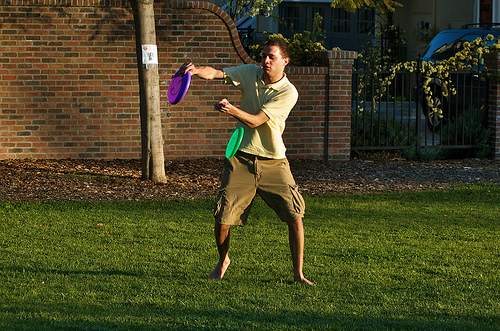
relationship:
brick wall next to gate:
[0, 0, 359, 160] [349, 52, 488, 155]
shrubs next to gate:
[349, 102, 491, 157] [349, 52, 488, 155]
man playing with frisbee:
[181, 37, 316, 287] [222, 127, 245, 159]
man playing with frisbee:
[181, 37, 316, 287] [165, 60, 192, 104]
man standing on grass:
[181, 37, 316, 287] [1, 181, 498, 329]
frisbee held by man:
[165, 60, 192, 104] [181, 37, 316, 287]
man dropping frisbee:
[181, 37, 316, 287] [222, 127, 245, 159]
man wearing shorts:
[181, 37, 316, 287] [213, 150, 305, 225]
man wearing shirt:
[181, 37, 316, 287] [219, 63, 300, 160]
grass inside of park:
[1, 181, 498, 329] [1, 1, 499, 331]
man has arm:
[181, 37, 316, 287] [227, 87, 298, 128]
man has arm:
[181, 37, 316, 287] [194, 63, 254, 82]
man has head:
[181, 37, 316, 287] [259, 37, 291, 76]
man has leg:
[181, 37, 316, 287] [286, 213, 306, 275]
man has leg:
[181, 37, 316, 287] [213, 220, 232, 256]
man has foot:
[181, 37, 316, 287] [294, 272, 317, 288]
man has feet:
[181, 37, 316, 287] [210, 253, 233, 278]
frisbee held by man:
[222, 127, 245, 159] [181, 37, 316, 287]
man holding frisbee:
[181, 37, 316, 287] [222, 127, 245, 159]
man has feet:
[181, 37, 316, 287] [210, 253, 317, 288]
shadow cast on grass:
[2, 296, 498, 331] [1, 181, 498, 329]